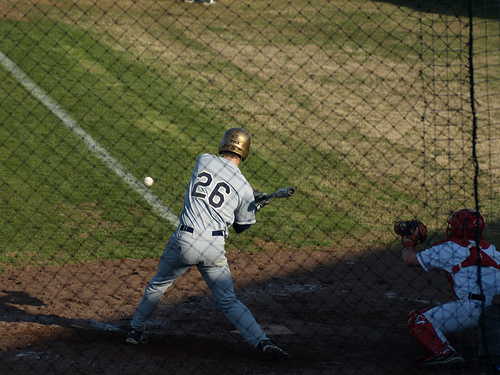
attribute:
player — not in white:
[112, 101, 330, 348]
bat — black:
[253, 184, 297, 200]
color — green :
[23, 66, 137, 136]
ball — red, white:
[133, 168, 158, 195]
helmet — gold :
[212, 120, 262, 155]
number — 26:
[191, 171, 231, 209]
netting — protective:
[2, 1, 498, 372]